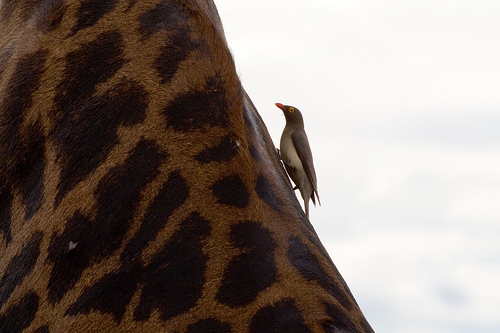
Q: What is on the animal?
A: A small bird.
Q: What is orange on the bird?
A: The birds beek.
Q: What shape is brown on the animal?
A: Heart shape.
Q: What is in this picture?
A: To animals.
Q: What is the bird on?
A: Animal.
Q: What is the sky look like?
A: Cloudy.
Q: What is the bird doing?
A: Resting.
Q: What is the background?
A: White and Boy Scout.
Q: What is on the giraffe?
A: Bird.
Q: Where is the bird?
A: On a giraffe's back.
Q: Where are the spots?
A: On the giraffe.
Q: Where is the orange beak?
A: On the bird.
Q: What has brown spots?
A: A giraffe.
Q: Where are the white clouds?
A: In the sky.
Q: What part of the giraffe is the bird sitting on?
A: The neck.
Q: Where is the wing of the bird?
A: On the side of it's body.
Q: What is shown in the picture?
A: Part of a giraffe.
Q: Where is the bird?
A: On the giraffe's neck.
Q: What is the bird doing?
A: Eating bugs.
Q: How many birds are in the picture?
A: One.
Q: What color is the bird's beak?
A: Red.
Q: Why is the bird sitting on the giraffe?
A: For food.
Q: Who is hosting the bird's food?
A: The giraffe.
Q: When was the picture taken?
A: At daytime.